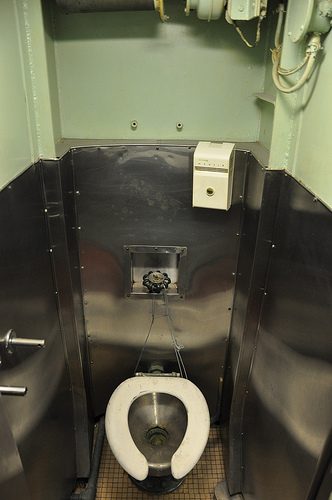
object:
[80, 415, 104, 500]
pipe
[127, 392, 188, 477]
toilet bowl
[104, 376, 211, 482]
toilet seat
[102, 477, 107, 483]
tile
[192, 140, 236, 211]
dispenser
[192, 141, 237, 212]
box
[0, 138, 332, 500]
wall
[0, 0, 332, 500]
bathroom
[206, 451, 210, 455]
tile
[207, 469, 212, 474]
tile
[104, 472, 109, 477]
tile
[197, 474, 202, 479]
tile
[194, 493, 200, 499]
tile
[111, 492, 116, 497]
tile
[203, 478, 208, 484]
tile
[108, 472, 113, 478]
tile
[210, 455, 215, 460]
tile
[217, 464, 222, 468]
tile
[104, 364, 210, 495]
toilet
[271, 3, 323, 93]
plumbing pipes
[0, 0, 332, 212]
green walls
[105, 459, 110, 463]
tile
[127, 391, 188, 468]
bowl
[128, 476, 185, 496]
base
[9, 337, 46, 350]
rod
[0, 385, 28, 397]
rod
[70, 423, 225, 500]
floor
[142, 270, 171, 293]
valve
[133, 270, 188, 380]
equipment